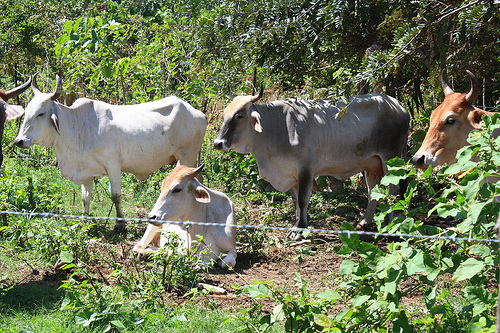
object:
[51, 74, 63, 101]
chunks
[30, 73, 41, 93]
chunks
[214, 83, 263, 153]
head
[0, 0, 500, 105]
plant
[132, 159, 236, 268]
cattle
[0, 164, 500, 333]
grass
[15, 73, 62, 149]
head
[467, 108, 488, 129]
ear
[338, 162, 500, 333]
leaf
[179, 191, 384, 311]
dirt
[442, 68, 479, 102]
cows horn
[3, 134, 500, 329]
ground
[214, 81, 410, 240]
cattle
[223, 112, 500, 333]
bush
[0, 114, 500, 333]
plant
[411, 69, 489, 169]
head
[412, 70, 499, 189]
bull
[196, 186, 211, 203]
ear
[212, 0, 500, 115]
tree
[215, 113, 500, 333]
bushes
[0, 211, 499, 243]
barbed wire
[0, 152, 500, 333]
floor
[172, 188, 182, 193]
eye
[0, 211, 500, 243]
wire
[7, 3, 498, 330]
field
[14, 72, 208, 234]
bull